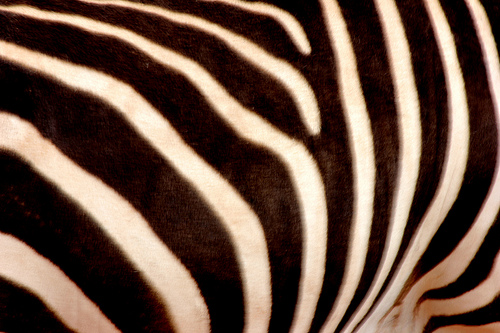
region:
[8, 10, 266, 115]
This is black and white.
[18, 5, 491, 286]
This is a zebra.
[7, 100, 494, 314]
This is zebra pattern.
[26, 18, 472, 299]
The zebra is striped.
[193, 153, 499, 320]
This patern is striped and wavy.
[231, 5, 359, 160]
The white stripes end here.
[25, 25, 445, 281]
This is a monochromatic pattern.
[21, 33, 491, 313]
This is an animal.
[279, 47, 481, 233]
This is made of fur.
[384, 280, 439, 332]
The black stripes end here.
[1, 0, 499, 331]
a close up of a zebras side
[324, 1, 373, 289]
a white zebra stripe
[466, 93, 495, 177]
dark brown hair on the zebra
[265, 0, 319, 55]
a short white zebra stripe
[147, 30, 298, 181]
a white stripe on the zebras rib cage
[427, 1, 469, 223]
wider zebra stripes are near the hind quarters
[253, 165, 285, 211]
brown hair is on a young zebra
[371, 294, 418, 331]
the zebra stripes meet at the arm pit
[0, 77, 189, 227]
zebras stripes running along the rib cage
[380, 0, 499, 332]
zebra stripes running along the hind quarters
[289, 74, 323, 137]
Round end of a white stripe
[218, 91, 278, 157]
Curve in a white stripe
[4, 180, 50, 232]
White spots in black fur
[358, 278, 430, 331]
Convergence of several white stripes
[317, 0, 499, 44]
Four white stripes on black fur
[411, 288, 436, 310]
End of a black stripe of fur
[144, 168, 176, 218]
Patch of black fur on a zebra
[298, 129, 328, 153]
Narrow gap between white stripes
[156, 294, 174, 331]
Brown fur in a white stripe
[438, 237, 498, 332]
Horizontal stripes on a zebra's body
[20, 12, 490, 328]
a close up of something dark brown or black striped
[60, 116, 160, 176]
part of the object is dark brown or black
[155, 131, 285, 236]
the other part is white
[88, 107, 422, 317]
it could possibly be a zebra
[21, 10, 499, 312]
it's an interesting picture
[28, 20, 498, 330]
it could be a close up of something else, though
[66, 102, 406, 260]
a dark background --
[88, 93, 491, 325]
stripes or something similar to stripes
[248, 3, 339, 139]
these two white stripes are not complete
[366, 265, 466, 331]
the stripes are all joined right here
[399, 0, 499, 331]
Long white stripe next to black stripe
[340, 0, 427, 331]
Long white stripe next to black stripe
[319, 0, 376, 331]
Long white stripe next to black stripe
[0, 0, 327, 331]
Long white stripe next to black stripe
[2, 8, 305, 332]
Long black stripe next to white stripe